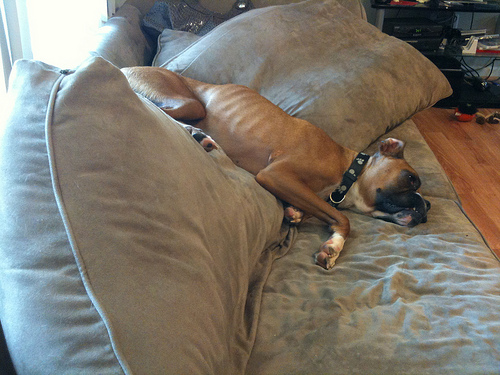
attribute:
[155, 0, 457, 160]
cushion — brown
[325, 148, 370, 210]
collar — black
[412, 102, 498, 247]
floor — hardwood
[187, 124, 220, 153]
paw — white 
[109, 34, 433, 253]
dog — big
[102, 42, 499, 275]
dog — black, brown 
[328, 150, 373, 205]
collar — black 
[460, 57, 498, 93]
wires — electrical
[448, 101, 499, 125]
toys — dog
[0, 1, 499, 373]
couch — gray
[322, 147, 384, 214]
collar — black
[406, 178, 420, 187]
eye — brown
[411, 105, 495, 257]
floor — brown, wooden 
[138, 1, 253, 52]
denim — blue